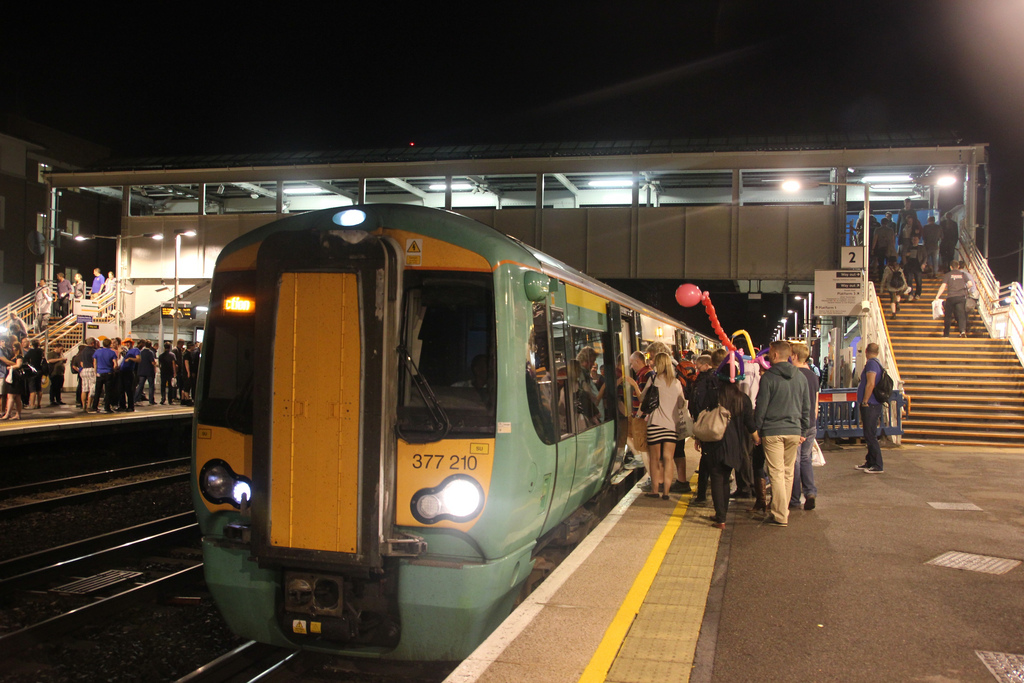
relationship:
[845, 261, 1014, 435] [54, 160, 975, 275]
stairway to bridge